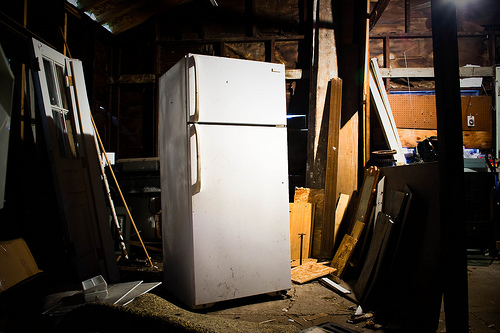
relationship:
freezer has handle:
[156, 52, 297, 310] [181, 118, 204, 192]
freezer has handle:
[156, 52, 297, 310] [186, 53, 204, 123]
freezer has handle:
[156, 52, 297, 310] [179, 51, 204, 121]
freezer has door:
[156, 52, 297, 310] [181, 52, 293, 127]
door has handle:
[179, 120, 296, 303] [182, 117, 207, 197]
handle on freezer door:
[184, 54, 202, 124] [181, 50, 290, 128]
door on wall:
[28, 36, 123, 283] [6, 10, 147, 284]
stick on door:
[97, 132, 158, 277] [28, 36, 123, 283]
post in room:
[424, 4, 478, 329] [1, 1, 493, 331]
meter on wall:
[464, 113, 475, 128] [388, 88, 497, 148]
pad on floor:
[120, 288, 303, 331] [55, 257, 497, 331]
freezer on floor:
[156, 52, 297, 310] [55, 257, 497, 331]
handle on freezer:
[183, 123, 203, 197] [156, 52, 297, 310]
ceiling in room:
[62, 0, 308, 36] [1, 1, 493, 331]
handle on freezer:
[184, 54, 202, 124] [181, 52, 289, 126]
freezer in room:
[156, 52, 297, 310] [1, 1, 493, 331]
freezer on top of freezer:
[162, 39, 298, 131] [156, 52, 297, 310]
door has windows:
[28, 24, 142, 265] [33, 48, 85, 137]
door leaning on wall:
[28, 24, 142, 265] [2, 11, 125, 281]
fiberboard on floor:
[275, 208, 382, 297] [4, 239, 498, 331]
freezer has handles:
[156, 52, 297, 310] [184, 48, 207, 208]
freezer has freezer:
[156, 52, 297, 310] [156, 52, 297, 310]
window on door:
[37, 54, 90, 143] [28, 36, 123, 283]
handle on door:
[183, 123, 203, 197] [179, 120, 296, 303]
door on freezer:
[179, 120, 296, 303] [156, 52, 297, 310]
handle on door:
[184, 54, 202, 124] [181, 52, 293, 127]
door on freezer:
[181, 52, 293, 127] [154, 47, 288, 125]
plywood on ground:
[287, 253, 340, 286] [281, 258, 383, 331]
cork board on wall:
[379, 89, 492, 134] [367, 36, 494, 174]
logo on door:
[268, 63, 286, 75] [177, 48, 291, 128]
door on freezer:
[181, 52, 293, 127] [156, 52, 297, 310]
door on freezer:
[183, 121, 295, 309] [156, 52, 297, 310]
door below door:
[183, 121, 295, 309] [181, 52, 293, 127]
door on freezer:
[175, 52, 290, 131] [156, 52, 297, 310]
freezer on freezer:
[156, 52, 297, 310] [156, 52, 297, 310]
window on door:
[41, 55, 61, 108] [23, 32, 132, 289]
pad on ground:
[55, 288, 304, 332] [79, 283, 364, 331]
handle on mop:
[87, 106, 153, 265] [85, 107, 162, 277]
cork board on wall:
[385, 91, 498, 135] [385, 73, 437, 149]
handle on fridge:
[166, 46, 220, 226] [165, 74, 300, 331]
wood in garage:
[293, 68, 383, 275] [188, 39, 452, 274]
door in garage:
[28, 36, 123, 283] [65, 64, 451, 294]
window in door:
[41, 55, 61, 108] [25, 48, 130, 198]